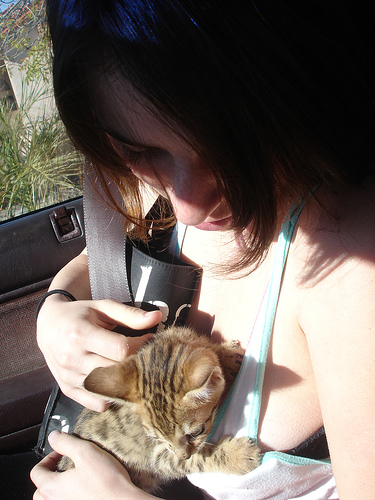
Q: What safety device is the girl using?
A: Seat belt.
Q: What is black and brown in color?
A: The kitten.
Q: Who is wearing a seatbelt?
A: The girl.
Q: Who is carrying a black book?
A: The girl.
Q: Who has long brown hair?
A: The girl.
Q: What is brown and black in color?
A: Baby kitten.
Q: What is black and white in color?
A: Small clutch.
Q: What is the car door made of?
A: Brown leather.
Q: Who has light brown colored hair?
A: The girl.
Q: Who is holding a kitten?
A: The woman.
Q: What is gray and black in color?
A: The kitten.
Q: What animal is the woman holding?
A: Kitten.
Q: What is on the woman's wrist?
A: Black bracelet.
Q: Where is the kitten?
A: On the woman's chest.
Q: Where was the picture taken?
A: In a car.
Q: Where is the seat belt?
A: Behind the woman's hand.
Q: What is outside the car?
A: Plants.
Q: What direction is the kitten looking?
A: Down.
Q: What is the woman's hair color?
A: Brown.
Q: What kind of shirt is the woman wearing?
A: Tank top.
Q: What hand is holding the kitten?
A: Left.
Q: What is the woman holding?
A: A cat.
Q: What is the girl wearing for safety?
A: Wearing a seatbelt.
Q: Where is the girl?
A: In a car.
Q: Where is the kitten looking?
A: Down.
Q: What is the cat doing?
A: Looking down.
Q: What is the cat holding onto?
A: The girl's shirt.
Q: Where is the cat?
A: In a car.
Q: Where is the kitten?
A: In the woman's arm.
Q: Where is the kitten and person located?
A: In a car.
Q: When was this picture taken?
A: Daytime.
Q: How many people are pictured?
A: One.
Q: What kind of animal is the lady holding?
A: A cat.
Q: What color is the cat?
A: Brown.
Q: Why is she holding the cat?
A: To keep him secure.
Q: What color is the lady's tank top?
A: Blue.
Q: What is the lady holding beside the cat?
A: A purse.